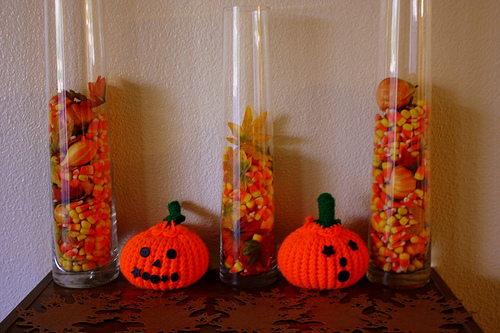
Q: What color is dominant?
A: Orange.